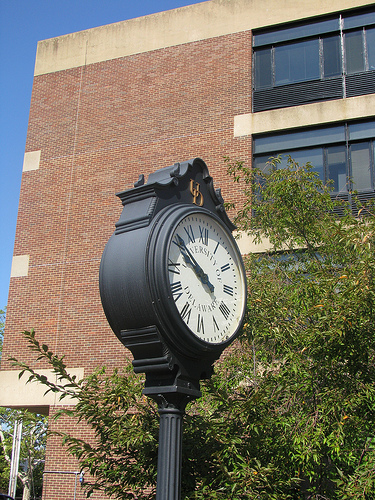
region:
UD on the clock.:
[181, 166, 210, 205]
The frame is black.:
[119, 158, 257, 368]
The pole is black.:
[150, 404, 193, 496]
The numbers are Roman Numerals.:
[173, 223, 243, 332]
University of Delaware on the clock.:
[179, 233, 232, 317]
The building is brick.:
[40, 32, 241, 169]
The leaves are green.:
[250, 202, 374, 498]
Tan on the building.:
[31, 3, 231, 72]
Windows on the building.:
[250, 33, 372, 225]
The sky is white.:
[2, 2, 89, 58]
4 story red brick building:
[132, 83, 182, 143]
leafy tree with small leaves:
[285, 410, 351, 480]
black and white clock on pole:
[112, 228, 232, 337]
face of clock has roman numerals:
[171, 284, 240, 365]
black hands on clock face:
[177, 250, 217, 298]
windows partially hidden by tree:
[270, 249, 327, 300]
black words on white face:
[181, 243, 223, 325]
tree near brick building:
[8, 412, 47, 490]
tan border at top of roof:
[70, 29, 184, 81]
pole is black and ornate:
[148, 383, 174, 481]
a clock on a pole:
[77, 155, 253, 385]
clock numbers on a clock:
[191, 290, 244, 340]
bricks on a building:
[57, 133, 129, 208]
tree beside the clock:
[226, 311, 349, 459]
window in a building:
[250, 12, 356, 110]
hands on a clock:
[176, 239, 218, 294]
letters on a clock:
[182, 178, 212, 204]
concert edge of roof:
[35, 13, 213, 63]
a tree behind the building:
[19, 439, 43, 495]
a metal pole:
[7, 416, 32, 488]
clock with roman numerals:
[164, 203, 244, 349]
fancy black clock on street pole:
[100, 153, 250, 493]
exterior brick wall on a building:
[49, 440, 79, 492]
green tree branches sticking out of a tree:
[14, 331, 148, 492]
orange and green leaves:
[309, 266, 362, 336]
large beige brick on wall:
[4, 366, 66, 408]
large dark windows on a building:
[227, 12, 373, 235]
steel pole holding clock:
[143, 393, 183, 499]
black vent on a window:
[245, 76, 350, 112]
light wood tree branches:
[4, 414, 40, 498]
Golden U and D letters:
[189, 180, 203, 206]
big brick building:
[21, 3, 370, 498]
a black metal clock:
[100, 158, 246, 389]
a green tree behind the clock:
[9, 152, 372, 495]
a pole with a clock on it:
[141, 387, 196, 498]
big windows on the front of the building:
[246, 3, 372, 109]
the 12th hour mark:
[197, 223, 209, 246]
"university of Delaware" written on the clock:
[180, 241, 221, 311]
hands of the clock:
[177, 234, 214, 294]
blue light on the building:
[79, 472, 83, 485]